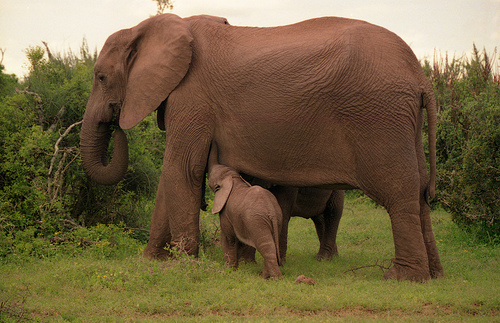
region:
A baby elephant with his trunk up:
[207, 143, 289, 277]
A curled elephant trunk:
[81, 10, 141, 190]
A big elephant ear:
[116, 13, 193, 130]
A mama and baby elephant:
[77, 10, 446, 283]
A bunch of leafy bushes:
[0, 50, 155, 224]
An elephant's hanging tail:
[420, 73, 442, 210]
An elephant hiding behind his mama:
[248, 165, 342, 262]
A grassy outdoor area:
[3, 184, 497, 308]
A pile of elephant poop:
[293, 271, 318, 288]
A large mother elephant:
[78, 10, 440, 280]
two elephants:
[77, 23, 450, 279]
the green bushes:
[441, 113, 498, 175]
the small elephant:
[205, 165, 298, 278]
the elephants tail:
[422, 98, 444, 190]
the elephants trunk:
[77, 102, 134, 182]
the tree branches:
[50, 115, 72, 181]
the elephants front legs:
[140, 171, 206, 256]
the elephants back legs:
[385, 195, 447, 280]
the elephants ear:
[117, 45, 192, 130]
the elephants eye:
[93, 70, 105, 84]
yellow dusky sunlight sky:
[0, 3, 499, 83]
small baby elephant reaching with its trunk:
[205, 136, 287, 281]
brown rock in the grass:
[290, 271, 321, 288]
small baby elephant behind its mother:
[241, 171, 346, 264]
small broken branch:
[344, 253, 398, 277]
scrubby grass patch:
[1, 190, 498, 320]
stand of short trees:
[0, 0, 499, 262]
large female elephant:
[77, 12, 447, 280]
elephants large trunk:
[76, 100, 128, 187]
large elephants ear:
[115, 11, 193, 132]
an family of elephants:
[79, 11, 459, 282]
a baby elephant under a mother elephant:
[200, 143, 294, 287]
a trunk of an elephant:
[73, 110, 136, 190]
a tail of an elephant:
[420, 77, 444, 214]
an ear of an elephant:
[116, 14, 199, 134]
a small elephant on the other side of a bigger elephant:
[278, 170, 348, 270]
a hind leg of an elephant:
[367, 78, 434, 290]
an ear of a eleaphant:
[206, 175, 231, 215]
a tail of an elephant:
[268, 211, 283, 266]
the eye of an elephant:
[93, 68, 112, 87]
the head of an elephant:
[79, 10, 174, 122]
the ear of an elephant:
[114, 7, 196, 134]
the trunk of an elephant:
[73, 90, 138, 192]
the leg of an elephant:
[361, 145, 439, 286]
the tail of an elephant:
[416, 75, 442, 202]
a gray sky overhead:
[0, 0, 499, 85]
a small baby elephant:
[200, 135, 294, 285]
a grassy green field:
[1, 187, 498, 322]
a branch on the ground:
[340, 253, 397, 279]